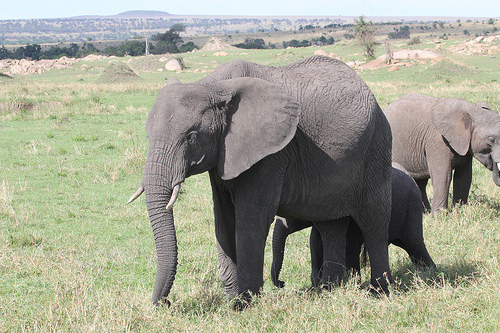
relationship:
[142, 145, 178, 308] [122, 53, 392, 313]
trunk of elephant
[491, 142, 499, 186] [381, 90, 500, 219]
trunk of elephant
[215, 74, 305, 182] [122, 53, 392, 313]
left ear of elephant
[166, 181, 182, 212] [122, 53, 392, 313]
tusk of elephant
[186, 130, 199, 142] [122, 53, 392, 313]
left eye of elephant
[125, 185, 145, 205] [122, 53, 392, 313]
tusk of elephant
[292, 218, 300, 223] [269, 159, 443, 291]
right eye of elephant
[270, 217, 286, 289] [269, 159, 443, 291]
trunk of elephant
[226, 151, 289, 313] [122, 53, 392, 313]
left leg of elephant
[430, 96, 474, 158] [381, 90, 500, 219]
right ear of elephant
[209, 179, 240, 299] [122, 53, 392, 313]
front leg of elephant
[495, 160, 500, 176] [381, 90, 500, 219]
tusk of elephant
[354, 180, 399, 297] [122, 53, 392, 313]
back leg of elephant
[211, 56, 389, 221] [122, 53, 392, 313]
body of elephant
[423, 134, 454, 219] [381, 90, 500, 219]
leg of elephant